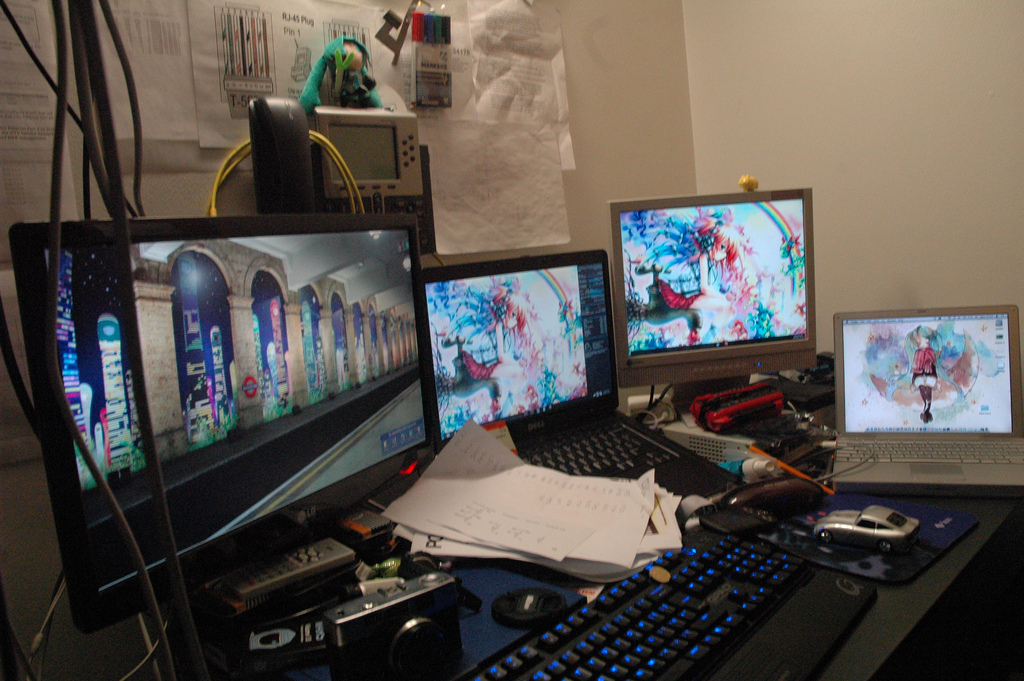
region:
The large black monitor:
[6, 199, 474, 577]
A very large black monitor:
[15, 203, 467, 603]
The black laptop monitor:
[409, 235, 666, 407]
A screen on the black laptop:
[420, 229, 648, 436]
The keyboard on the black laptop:
[498, 418, 691, 516]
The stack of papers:
[385, 425, 677, 600]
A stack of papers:
[394, 433, 676, 583]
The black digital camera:
[311, 566, 468, 665]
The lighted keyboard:
[447, 522, 795, 665]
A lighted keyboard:
[485, 528, 809, 668]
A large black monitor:
[11, 205, 486, 550]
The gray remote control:
[222, 537, 365, 596]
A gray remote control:
[211, 540, 352, 599]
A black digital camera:
[293, 569, 472, 659]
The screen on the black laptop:
[412, 259, 640, 425]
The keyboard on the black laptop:
[529, 423, 679, 485]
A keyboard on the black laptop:
[524, 423, 679, 499]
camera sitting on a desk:
[319, 571, 463, 677]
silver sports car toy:
[808, 502, 922, 550]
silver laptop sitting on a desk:
[825, 305, 1022, 487]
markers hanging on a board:
[405, 6, 454, 115]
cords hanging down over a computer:
[0, 0, 215, 680]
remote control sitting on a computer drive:
[209, 536, 356, 607]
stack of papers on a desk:
[379, 419, 684, 584]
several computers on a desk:
[2, 186, 1020, 673]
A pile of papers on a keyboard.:
[381, 416, 683, 575]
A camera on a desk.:
[317, 563, 454, 671]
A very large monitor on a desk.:
[4, 213, 429, 607]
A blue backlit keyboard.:
[465, 522, 871, 671]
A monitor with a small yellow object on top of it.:
[604, 171, 814, 380]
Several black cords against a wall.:
[1, 0, 147, 213]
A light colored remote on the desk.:
[213, 528, 350, 596]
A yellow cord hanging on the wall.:
[204, 125, 364, 214]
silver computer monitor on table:
[569, 165, 883, 412]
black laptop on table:
[419, 241, 699, 517]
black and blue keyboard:
[425, 510, 837, 673]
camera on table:
[317, 567, 520, 678]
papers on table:
[377, 449, 738, 599]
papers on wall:
[378, 51, 635, 287]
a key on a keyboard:
[517, 636, 536, 659]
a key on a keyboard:
[528, 623, 561, 643]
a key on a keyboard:
[555, 614, 569, 634]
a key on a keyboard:
[569, 611, 580, 624]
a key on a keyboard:
[577, 599, 593, 615]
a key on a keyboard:
[601, 576, 615, 592]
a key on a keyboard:
[631, 590, 647, 603]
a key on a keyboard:
[625, 601, 644, 622]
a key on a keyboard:
[612, 610, 629, 624]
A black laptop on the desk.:
[411, 255, 699, 560]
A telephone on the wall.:
[231, 89, 485, 270]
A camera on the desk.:
[319, 587, 476, 679]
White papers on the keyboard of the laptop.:
[419, 437, 655, 586]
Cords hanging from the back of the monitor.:
[22, 9, 178, 234]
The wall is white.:
[563, 18, 1015, 216]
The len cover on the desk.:
[489, 584, 578, 626]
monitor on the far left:
[2, 216, 430, 621]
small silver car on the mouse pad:
[814, 505, 922, 551]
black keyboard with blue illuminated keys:
[465, 521, 807, 678]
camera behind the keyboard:
[325, 572, 465, 672]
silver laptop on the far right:
[833, 301, 1023, 499]